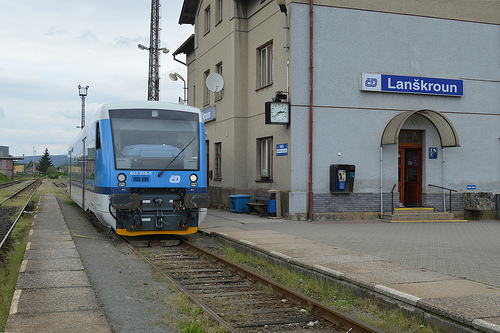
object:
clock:
[264, 90, 290, 125]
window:
[254, 134, 276, 183]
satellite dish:
[205, 73, 224, 92]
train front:
[94, 99, 207, 236]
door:
[398, 129, 426, 207]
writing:
[387, 77, 457, 93]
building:
[170, 0, 500, 221]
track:
[131, 243, 371, 333]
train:
[67, 101, 213, 247]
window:
[253, 37, 273, 92]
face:
[271, 103, 288, 122]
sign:
[356, 72, 464, 97]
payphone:
[329, 163, 356, 194]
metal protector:
[329, 163, 356, 194]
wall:
[284, 0, 499, 220]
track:
[0, 175, 41, 249]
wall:
[171, 0, 289, 217]